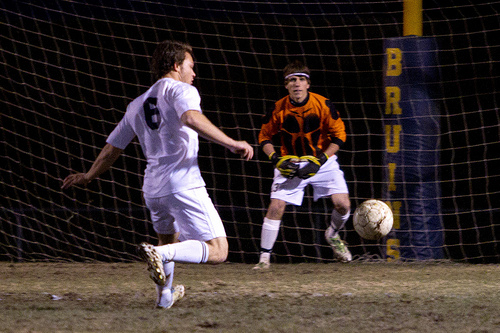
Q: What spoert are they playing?
A: Soccar.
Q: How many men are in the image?
A: Two.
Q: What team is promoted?
A: Bruins.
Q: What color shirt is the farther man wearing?
A: Orange and black.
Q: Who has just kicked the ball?
A: Man in white.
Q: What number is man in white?
A: Six.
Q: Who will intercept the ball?
A: Man in orange.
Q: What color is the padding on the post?
A: Blue.